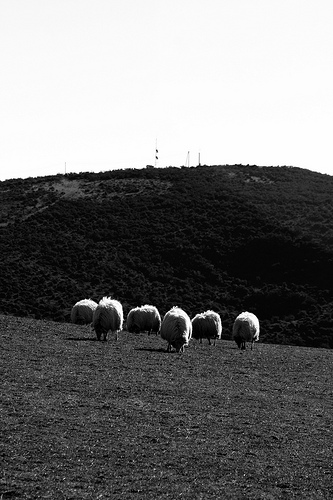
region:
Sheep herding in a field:
[52, 266, 322, 404]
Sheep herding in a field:
[169, 297, 267, 328]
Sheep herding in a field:
[56, 290, 141, 351]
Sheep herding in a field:
[118, 296, 203, 350]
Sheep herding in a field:
[151, 294, 247, 355]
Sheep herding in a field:
[189, 302, 257, 363]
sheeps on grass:
[61, 281, 264, 359]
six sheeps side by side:
[63, 289, 267, 355]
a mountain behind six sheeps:
[0, 149, 327, 359]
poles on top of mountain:
[56, 140, 214, 172]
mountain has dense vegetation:
[2, 158, 332, 319]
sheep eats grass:
[89, 296, 122, 346]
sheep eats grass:
[163, 301, 195, 358]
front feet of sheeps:
[96, 331, 111, 342]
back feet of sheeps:
[109, 327, 118, 340]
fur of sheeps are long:
[65, 293, 263, 355]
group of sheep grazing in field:
[64, 289, 270, 357]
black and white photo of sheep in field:
[3, 2, 331, 498]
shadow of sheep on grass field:
[59, 331, 108, 347]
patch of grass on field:
[45, 391, 116, 446]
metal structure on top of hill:
[150, 130, 161, 167]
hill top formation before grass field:
[0, 144, 332, 350]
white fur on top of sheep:
[100, 293, 116, 306]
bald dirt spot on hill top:
[47, 177, 95, 201]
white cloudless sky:
[9, 5, 330, 118]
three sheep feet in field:
[198, 337, 220, 349]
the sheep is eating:
[150, 302, 191, 372]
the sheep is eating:
[226, 312, 277, 369]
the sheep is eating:
[86, 287, 138, 356]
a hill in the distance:
[62, 130, 326, 271]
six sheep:
[50, 289, 268, 367]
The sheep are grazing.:
[48, 290, 283, 383]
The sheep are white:
[55, 282, 283, 369]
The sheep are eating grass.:
[56, 289, 277, 367]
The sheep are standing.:
[61, 279, 267, 387]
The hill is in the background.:
[1, 163, 329, 351]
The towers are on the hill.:
[140, 138, 204, 173]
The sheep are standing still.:
[62, 293, 280, 359]